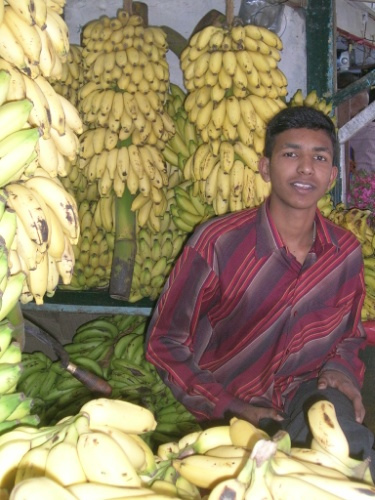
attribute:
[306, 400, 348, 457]
banana — ripe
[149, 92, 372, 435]
man — sitting down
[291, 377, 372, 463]
cloth — black 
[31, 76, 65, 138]
banana — large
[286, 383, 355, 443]
pants — black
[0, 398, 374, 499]
bananas — yellow 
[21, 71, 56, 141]
banana — ripe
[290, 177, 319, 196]
mouth — slightly opened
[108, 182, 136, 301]
pole — covered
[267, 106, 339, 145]
hair — dark 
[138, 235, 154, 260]
banana — green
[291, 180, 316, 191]
teeth — white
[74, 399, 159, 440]
banana — ripe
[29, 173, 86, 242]
banana — ripe